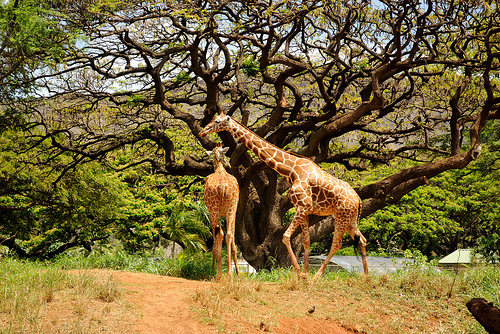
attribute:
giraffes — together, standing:
[202, 109, 356, 308]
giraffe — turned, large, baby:
[201, 149, 250, 272]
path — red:
[79, 256, 268, 332]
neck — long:
[226, 122, 291, 172]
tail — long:
[209, 185, 229, 237]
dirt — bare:
[141, 282, 287, 331]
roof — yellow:
[440, 242, 477, 265]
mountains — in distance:
[138, 79, 432, 135]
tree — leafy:
[30, 145, 210, 265]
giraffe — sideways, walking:
[200, 67, 380, 280]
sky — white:
[85, 22, 235, 79]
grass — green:
[148, 242, 211, 277]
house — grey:
[320, 254, 430, 280]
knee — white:
[273, 217, 305, 252]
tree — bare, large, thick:
[48, 12, 483, 267]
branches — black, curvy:
[115, 7, 469, 99]